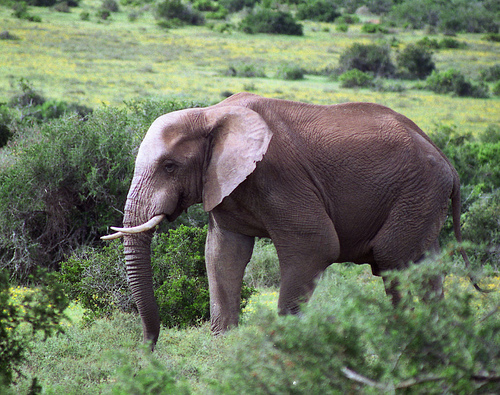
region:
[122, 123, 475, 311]
A big Brown elephant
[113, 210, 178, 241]
A white tusk of an elephant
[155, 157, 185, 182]
An eye of an elephant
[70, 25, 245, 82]
Small yellow flowers in the field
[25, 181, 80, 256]
A dry wood of a branch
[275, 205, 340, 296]
Bent ankle of a feet of an elephant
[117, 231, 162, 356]
Trunk of an elephant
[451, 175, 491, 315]
The tail of an Elephant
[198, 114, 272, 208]
The ear of an elephant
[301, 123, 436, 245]
The skin of an elephant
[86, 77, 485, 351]
A gray elephant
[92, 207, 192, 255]
White elephant tusks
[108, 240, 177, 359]
A wrinkly elephant trunk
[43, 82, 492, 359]
An elephant in the brush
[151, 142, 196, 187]
The eye of an elephant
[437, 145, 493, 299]
The tail of an elephant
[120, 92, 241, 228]
The head of an elephant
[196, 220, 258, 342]
An elephant leg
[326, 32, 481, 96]
Small green bushes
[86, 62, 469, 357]
grey elephant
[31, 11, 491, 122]
green and yellow field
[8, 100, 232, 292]
bushes next to an elephant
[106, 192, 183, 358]
long grey elephant trunk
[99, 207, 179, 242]
small white tusks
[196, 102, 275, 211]
big flat grey ear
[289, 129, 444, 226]
wrinkled elephant hide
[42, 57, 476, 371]
elephant surrounded by bushes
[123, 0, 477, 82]
grouped bushes in a small field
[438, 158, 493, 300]
long thin tail of an elephant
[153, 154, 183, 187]
Elephant has large eye.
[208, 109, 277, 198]
Elephant has large gray ear.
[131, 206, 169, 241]
Elephant has white tusk.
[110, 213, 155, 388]
Elephant has long gray tusk.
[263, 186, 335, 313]
Elephant has gray wrinkly leg.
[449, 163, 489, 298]
Elephant has long gray tail.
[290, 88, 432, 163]
Elephant has gray wrinkly back.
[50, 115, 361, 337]
Elephant is walking thru the grass.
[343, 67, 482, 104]
Green bushes in distance.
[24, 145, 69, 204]
Leaves on trees are green.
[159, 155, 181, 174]
eye of the elephant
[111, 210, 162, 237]
left tusk of the elephant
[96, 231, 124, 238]
right tusk of the elephant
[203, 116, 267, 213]
left ear of the elephant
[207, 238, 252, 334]
right leg of the elephant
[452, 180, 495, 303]
the tail of the elephant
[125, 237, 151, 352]
trunk of the elephant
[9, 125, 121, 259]
large shrubbery in the field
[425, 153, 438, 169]
bump on the elephant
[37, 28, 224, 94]
large open field